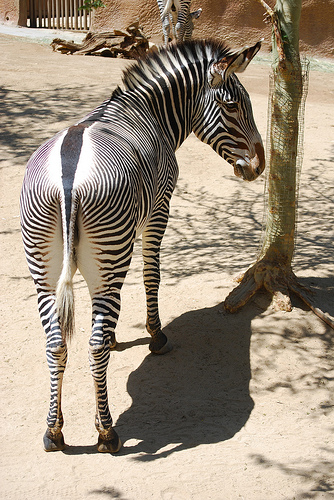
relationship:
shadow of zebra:
[104, 268, 280, 465] [13, 26, 278, 455]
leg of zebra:
[132, 208, 179, 357] [13, 26, 278, 455]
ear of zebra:
[229, 38, 266, 84] [13, 26, 278, 455]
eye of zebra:
[222, 99, 239, 111] [13, 26, 278, 455]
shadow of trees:
[255, 431, 332, 499] [249, 15, 326, 323]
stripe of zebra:
[60, 93, 114, 254] [13, 26, 278, 455]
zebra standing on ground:
[13, 26, 278, 455] [2, 32, 332, 498]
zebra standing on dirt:
[13, 26, 278, 455] [1, 30, 328, 498]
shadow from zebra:
[60, 239, 292, 462] [13, 26, 278, 455]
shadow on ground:
[87, 477, 128, 499] [2, 32, 332, 498]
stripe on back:
[60, 87, 113, 266] [31, 98, 155, 193]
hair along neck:
[115, 37, 227, 94] [101, 41, 218, 146]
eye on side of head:
[222, 99, 239, 111] [191, 40, 271, 180]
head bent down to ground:
[169, 10, 201, 45] [2, 32, 332, 498]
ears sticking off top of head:
[213, 34, 262, 89] [190, 39, 268, 194]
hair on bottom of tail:
[55, 277, 76, 344] [45, 200, 88, 338]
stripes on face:
[203, 82, 258, 150] [195, 59, 275, 181]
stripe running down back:
[60, 93, 114, 254] [49, 90, 151, 226]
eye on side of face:
[220, 99, 245, 116] [192, 48, 277, 184]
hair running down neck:
[115, 37, 227, 94] [122, 39, 202, 154]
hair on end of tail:
[51, 281, 76, 341] [54, 181, 81, 344]